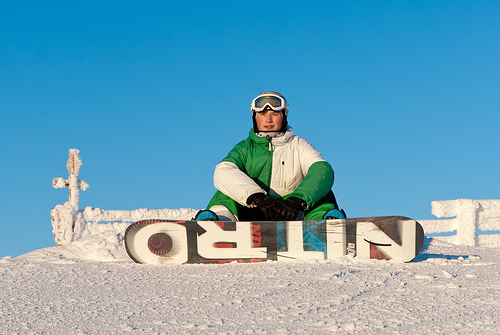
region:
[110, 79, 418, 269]
man with snow board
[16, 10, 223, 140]
Large body of skies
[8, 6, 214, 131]
Large body of blue skies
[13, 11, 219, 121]
The sky is dark blue in color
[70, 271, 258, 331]
A patch of snow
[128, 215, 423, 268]
The word "Nitro" is written on the surfboard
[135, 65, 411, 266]
A person is sitting down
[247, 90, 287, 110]
The person has snow goggles on his head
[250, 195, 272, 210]
Black glove on a person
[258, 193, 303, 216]
Gloves on a person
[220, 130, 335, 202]
Green and white colored jacket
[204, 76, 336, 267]
man in snow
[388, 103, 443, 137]
white clouds in blue sky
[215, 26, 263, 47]
white clouds in blue sky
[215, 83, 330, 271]
man in snow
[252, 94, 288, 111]
white goggles on head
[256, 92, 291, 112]
tan helmet on head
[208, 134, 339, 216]
white and green snow suit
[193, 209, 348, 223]
blue and black boots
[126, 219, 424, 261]
multi colored snow board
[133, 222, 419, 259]
white letters on snow board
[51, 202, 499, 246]
fence covered in snow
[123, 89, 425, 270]
person with snowboard on feet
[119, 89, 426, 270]
person sitting in snow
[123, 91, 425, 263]
person sitting on hill